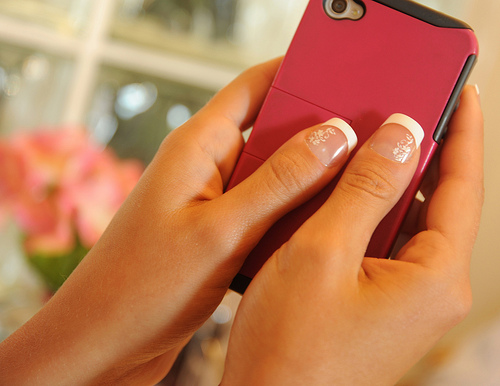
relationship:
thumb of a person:
[297, 111, 430, 278] [1, 52, 486, 384]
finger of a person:
[448, 80, 490, 242] [143, 85, 408, 372]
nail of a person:
[371, 105, 428, 168] [1, 52, 486, 384]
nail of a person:
[302, 115, 359, 170] [1, 52, 486, 384]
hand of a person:
[215, 77, 488, 384] [1, 52, 486, 384]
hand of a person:
[1, 52, 361, 384] [1, 52, 486, 384]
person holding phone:
[110, 64, 471, 379] [320, 47, 440, 97]